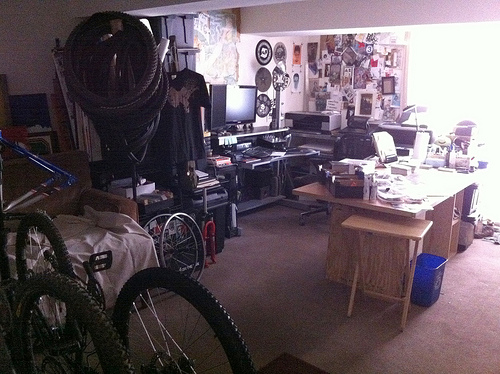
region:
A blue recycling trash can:
[410, 248, 443, 306]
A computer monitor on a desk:
[227, 82, 257, 126]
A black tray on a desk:
[317, 160, 362, 197]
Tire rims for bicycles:
[147, 213, 208, 280]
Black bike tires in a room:
[117, 266, 264, 372]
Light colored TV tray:
[337, 207, 429, 332]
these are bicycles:
[34, 255, 184, 335]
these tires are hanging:
[79, 29, 162, 121]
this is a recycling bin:
[416, 244, 453, 290]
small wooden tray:
[335, 208, 436, 340]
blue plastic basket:
[410, 244, 451, 313]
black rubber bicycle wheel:
[108, 258, 260, 372]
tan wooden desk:
[286, 141, 482, 310]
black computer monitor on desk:
[206, 78, 266, 137]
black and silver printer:
[278, 103, 345, 138]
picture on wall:
[377, 71, 399, 101]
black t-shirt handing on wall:
[165, 55, 217, 175]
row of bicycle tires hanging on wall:
[53, 8, 171, 134]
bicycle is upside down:
[1, 211, 255, 372]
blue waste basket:
[413, 250, 447, 303]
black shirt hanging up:
[162, 65, 210, 163]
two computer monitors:
[208, 84, 259, 134]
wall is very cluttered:
[307, 36, 409, 118]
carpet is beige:
[88, 200, 499, 372]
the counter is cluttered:
[293, 150, 479, 260]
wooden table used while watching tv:
[343, 210, 433, 327]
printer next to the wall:
[281, 111, 340, 133]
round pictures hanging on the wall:
[255, 36, 290, 121]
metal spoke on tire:
[130, 299, 162, 362]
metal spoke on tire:
[138, 296, 189, 358]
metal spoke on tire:
[144, 285, 170, 357]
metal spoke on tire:
[160, 289, 175, 356]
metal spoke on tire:
[175, 298, 192, 363]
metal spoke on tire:
[176, 325, 211, 360]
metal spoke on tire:
[185, 313, 203, 346]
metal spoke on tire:
[28, 227, 45, 261]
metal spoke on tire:
[25, 226, 36, 267]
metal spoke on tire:
[197, 343, 219, 366]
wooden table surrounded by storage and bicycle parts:
[13, 17, 488, 366]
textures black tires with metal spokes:
[5, 204, 254, 369]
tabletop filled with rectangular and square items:
[290, 118, 480, 218]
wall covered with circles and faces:
[242, 32, 306, 132]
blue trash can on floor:
[407, 246, 450, 311]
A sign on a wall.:
[255, 94, 275, 116]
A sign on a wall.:
[253, 70, 271, 90]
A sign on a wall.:
[253, 40, 270, 65]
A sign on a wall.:
[271, 40, 282, 60]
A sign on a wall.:
[270, 67, 285, 89]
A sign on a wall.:
[290, 42, 301, 67]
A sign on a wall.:
[305, 42, 318, 59]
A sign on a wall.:
[303, 76, 320, 93]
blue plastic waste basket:
[406, 249, 451, 311]